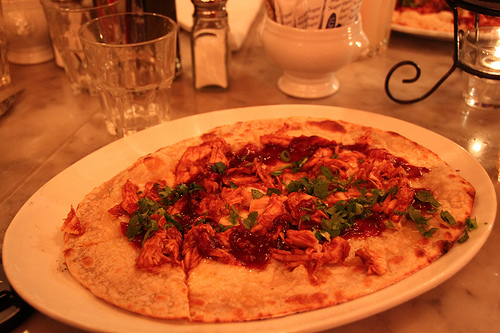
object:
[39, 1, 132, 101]
glass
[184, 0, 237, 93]
salt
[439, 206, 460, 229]
vegetable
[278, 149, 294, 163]
vegetable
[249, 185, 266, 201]
vegetable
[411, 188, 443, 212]
vegetable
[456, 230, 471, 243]
vegetable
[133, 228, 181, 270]
shredded meat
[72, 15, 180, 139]
glass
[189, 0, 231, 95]
shaker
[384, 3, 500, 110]
metallic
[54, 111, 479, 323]
food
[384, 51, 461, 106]
candle holder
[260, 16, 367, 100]
cup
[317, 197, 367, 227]
herb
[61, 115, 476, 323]
pizza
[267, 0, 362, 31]
sugar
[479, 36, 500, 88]
candle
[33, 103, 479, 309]
flatbread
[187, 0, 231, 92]
salt shaker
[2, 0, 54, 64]
cup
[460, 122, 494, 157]
reflection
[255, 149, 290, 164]
sauce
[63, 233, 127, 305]
tan color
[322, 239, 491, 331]
edge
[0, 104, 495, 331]
plate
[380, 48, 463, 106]
wire.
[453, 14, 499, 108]
glass holder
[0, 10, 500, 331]
table